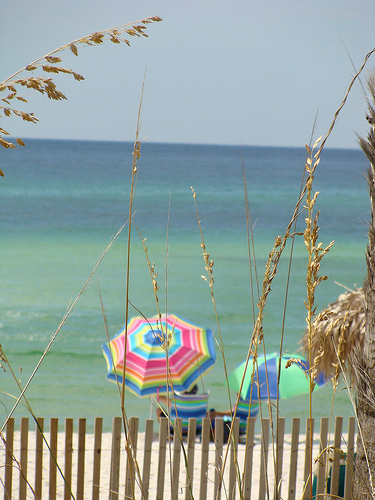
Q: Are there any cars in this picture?
A: No, there are no cars.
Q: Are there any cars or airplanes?
A: No, there are no cars or airplanes.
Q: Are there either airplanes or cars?
A: No, there are no cars or airplanes.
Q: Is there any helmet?
A: No, there are no helmets.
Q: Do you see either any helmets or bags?
A: No, there are no helmets or bags.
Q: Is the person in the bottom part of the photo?
A: Yes, the person is in the bottom of the image.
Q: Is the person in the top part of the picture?
A: No, the person is in the bottom of the image.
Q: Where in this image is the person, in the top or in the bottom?
A: The person is in the bottom of the image.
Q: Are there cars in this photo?
A: No, there are no cars.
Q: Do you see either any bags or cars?
A: No, there are no cars or bags.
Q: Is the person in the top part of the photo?
A: No, the person is in the bottom of the image.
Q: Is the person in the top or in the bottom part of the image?
A: The person is in the bottom of the image.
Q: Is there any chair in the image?
A: Yes, there is a chair.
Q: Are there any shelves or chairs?
A: Yes, there is a chair.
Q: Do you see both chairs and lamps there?
A: No, there is a chair but no lamps.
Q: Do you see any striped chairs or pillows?
A: Yes, there is a striped chair.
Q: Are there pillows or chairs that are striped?
A: Yes, the chair is striped.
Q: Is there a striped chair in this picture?
A: Yes, there is a striped chair.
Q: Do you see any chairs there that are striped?
A: Yes, there is a chair that is striped.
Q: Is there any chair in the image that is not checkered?
A: Yes, there is a striped chair.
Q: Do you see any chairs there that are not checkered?
A: Yes, there is a striped chair.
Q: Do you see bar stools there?
A: No, there are no bar stools.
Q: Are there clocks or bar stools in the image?
A: No, there are no bar stools or clocks.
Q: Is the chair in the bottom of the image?
A: Yes, the chair is in the bottom of the image.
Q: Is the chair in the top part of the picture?
A: No, the chair is in the bottom of the image.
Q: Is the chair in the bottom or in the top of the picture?
A: The chair is in the bottom of the image.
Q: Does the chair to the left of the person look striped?
A: Yes, the chair is striped.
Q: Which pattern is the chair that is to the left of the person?
A: The chair is striped.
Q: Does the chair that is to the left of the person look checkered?
A: No, the chair is striped.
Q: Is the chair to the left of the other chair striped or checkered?
A: The chair is striped.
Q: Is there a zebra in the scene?
A: No, there are no zebras.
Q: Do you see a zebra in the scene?
A: No, there are no zebras.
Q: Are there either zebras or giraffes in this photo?
A: No, there are no zebras or giraffes.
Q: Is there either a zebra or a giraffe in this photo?
A: No, there are no zebras or giraffes.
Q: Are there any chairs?
A: Yes, there is a chair.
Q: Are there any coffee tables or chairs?
A: Yes, there is a chair.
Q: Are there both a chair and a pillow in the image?
A: No, there is a chair but no pillows.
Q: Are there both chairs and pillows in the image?
A: No, there is a chair but no pillows.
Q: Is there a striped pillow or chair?
A: Yes, there is a striped chair.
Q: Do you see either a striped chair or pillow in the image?
A: Yes, there is a striped chair.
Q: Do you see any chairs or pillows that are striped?
A: Yes, the chair is striped.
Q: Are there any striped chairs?
A: Yes, there is a striped chair.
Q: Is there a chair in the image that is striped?
A: Yes, there is a chair that is striped.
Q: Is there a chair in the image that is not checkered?
A: Yes, there is a striped chair.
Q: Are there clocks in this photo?
A: No, there are no clocks.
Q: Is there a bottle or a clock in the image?
A: No, there are no clocks or bottles.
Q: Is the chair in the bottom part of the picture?
A: Yes, the chair is in the bottom of the image.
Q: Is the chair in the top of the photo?
A: No, the chair is in the bottom of the image.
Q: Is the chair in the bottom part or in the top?
A: The chair is in the bottom of the image.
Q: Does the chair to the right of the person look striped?
A: Yes, the chair is striped.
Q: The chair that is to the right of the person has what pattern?
A: The chair is striped.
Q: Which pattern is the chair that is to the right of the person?
A: The chair is striped.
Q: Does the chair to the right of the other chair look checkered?
A: No, the chair is striped.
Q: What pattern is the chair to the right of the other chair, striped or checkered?
A: The chair is striped.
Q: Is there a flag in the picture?
A: No, there are no flags.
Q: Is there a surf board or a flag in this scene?
A: No, there are no flags or surfboards.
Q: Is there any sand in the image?
A: Yes, there is sand.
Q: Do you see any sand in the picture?
A: Yes, there is sand.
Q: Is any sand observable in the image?
A: Yes, there is sand.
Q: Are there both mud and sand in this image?
A: No, there is sand but no mud.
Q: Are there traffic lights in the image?
A: No, there are no traffic lights.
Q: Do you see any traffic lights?
A: No, there are no traffic lights.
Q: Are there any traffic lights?
A: No, there are no traffic lights.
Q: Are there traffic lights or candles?
A: No, there are no traffic lights or candles.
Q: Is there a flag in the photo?
A: No, there are no flags.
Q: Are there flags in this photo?
A: No, there are no flags.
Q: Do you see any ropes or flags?
A: No, there are no flags or ropes.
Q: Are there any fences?
A: Yes, there is a fence.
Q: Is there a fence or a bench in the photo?
A: Yes, there is a fence.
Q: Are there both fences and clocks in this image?
A: No, there is a fence but no clocks.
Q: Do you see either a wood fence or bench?
A: Yes, there is a wood fence.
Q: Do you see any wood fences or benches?
A: Yes, there is a wood fence.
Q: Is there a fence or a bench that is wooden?
A: Yes, the fence is wooden.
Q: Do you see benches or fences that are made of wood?
A: Yes, the fence is made of wood.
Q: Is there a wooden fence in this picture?
A: Yes, there is a wood fence.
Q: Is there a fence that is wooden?
A: Yes, there is a fence that is wooden.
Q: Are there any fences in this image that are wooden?
A: Yes, there is a fence that is wooden.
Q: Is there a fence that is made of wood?
A: Yes, there is a fence that is made of wood.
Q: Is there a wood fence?
A: Yes, there is a fence that is made of wood.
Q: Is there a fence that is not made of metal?
A: Yes, there is a fence that is made of wood.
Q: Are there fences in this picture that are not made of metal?
A: Yes, there is a fence that is made of wood.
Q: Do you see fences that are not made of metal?
A: Yes, there is a fence that is made of wood.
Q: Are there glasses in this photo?
A: No, there are no glasses.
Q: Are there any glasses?
A: No, there are no glasses.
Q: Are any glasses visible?
A: No, there are no glasses.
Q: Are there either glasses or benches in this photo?
A: No, there are no glasses or benches.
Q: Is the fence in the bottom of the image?
A: Yes, the fence is in the bottom of the image.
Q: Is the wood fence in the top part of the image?
A: No, the fence is in the bottom of the image.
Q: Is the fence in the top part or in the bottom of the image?
A: The fence is in the bottom of the image.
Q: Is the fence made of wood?
A: Yes, the fence is made of wood.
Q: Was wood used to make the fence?
A: Yes, the fence is made of wood.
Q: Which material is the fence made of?
A: The fence is made of wood.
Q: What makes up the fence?
A: The fence is made of wood.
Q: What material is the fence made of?
A: The fence is made of wood.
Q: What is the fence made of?
A: The fence is made of wood.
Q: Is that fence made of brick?
A: No, the fence is made of wood.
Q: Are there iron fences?
A: No, there is a fence but it is made of wood.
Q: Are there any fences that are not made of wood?
A: No, there is a fence but it is made of wood.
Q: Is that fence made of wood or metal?
A: The fence is made of wood.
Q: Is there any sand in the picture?
A: Yes, there is sand.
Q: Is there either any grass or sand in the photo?
A: Yes, there is sand.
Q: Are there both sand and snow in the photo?
A: No, there is sand but no snow.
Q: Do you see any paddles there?
A: No, there are no paddles.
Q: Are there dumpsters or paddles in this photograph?
A: No, there are no paddles or dumpsters.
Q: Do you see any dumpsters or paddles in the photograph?
A: No, there are no paddles or dumpsters.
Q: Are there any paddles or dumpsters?
A: No, there are no paddles or dumpsters.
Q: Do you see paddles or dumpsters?
A: No, there are no paddles or dumpsters.